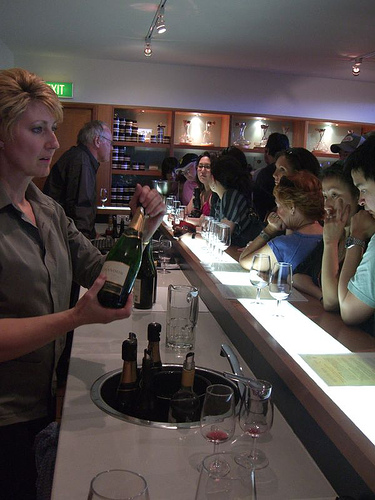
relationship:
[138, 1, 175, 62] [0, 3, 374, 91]
lighting on ceiling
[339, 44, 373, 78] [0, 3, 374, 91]
lighting on ceiling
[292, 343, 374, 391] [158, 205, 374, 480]
menu on bar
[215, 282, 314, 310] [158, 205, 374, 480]
menu on bar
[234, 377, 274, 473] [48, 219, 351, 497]
wine glass on bar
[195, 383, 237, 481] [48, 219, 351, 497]
wine glass on bar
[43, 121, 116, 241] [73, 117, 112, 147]
man has hair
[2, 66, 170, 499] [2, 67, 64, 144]
woman with hair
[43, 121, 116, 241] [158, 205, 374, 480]
man by bar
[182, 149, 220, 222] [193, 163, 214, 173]
woman with glasses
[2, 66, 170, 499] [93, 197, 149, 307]
woman opening bottle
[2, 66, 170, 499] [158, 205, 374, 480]
woman behind bar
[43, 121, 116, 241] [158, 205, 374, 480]
man behind bar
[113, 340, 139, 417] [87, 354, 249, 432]
bottle in sink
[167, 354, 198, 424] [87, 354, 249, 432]
bottle in sink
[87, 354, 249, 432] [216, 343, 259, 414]
sink with faucet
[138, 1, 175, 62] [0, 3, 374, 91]
lighting hanging from ceiling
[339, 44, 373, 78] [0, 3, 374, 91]
lighting hanging from ceiling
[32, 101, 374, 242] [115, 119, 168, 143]
shelves display product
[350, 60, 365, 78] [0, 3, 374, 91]
spotlight on ceiling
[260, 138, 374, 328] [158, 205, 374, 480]
people at bar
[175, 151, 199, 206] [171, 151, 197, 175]
man in cap